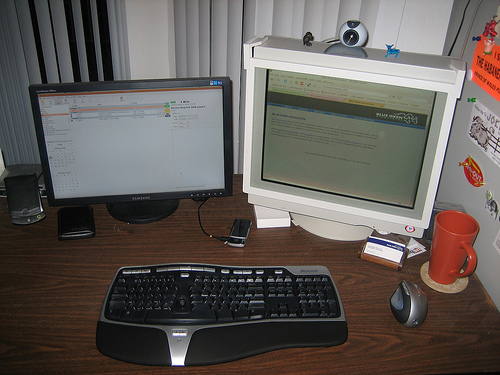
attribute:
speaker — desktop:
[4, 170, 46, 225]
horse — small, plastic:
[381, 41, 403, 61]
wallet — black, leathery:
[56, 200, 98, 240]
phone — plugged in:
[221, 217, 256, 249]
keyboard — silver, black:
[91, 259, 349, 364]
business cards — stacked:
[361, 233, 408, 266]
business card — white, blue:
[362, 234, 402, 263]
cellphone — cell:
[215, 212, 272, 273]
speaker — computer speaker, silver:
[2, 172, 54, 223]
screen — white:
[37, 89, 224, 198]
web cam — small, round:
[337, 18, 369, 49]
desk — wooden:
[0, 174, 499, 374]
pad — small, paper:
[244, 203, 297, 233]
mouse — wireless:
[363, 262, 443, 360]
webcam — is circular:
[338, 18, 370, 49]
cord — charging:
[188, 197, 224, 242]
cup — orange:
[415, 202, 487, 296]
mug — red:
[425, 206, 482, 287]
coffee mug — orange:
[428, 210, 480, 285]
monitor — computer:
[26, 75, 233, 208]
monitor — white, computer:
[242, 32, 468, 243]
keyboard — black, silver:
[96, 257, 353, 371]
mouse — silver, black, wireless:
[389, 277, 429, 327]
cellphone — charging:
[223, 217, 255, 249]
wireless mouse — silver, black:
[388, 280, 428, 327]